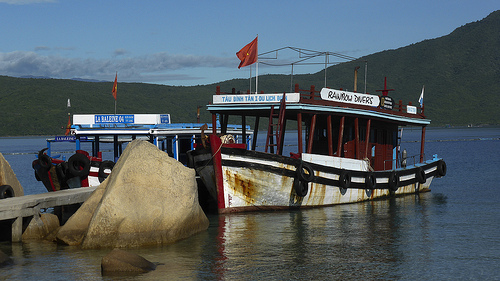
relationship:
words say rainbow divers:
[321, 89, 381, 106] [328, 92, 376, 105]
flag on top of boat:
[234, 40, 259, 69] [191, 36, 451, 214]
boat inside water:
[191, 36, 451, 214] [0, 129, 499, 278]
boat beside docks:
[191, 36, 451, 214] [3, 139, 208, 251]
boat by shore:
[191, 36, 451, 214] [4, 129, 256, 278]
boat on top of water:
[191, 36, 451, 214] [0, 129, 499, 278]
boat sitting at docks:
[191, 36, 451, 214] [3, 152, 202, 254]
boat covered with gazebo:
[191, 36, 451, 214] [252, 43, 371, 100]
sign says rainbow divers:
[212, 92, 295, 104] [328, 92, 376, 105]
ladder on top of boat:
[378, 77, 391, 103] [191, 36, 451, 214]